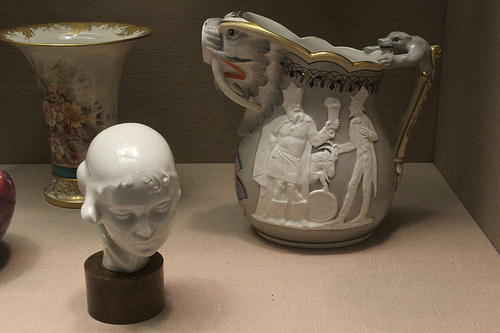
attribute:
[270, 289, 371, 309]
table — DISPLAY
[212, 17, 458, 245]
pitcher — ORNATE, LARGE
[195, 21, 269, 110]
head — ANIMAL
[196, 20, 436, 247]
vase — BLACK, GOLD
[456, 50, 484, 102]
wall — TAN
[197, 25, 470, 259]
pitcher — UNATTRACTIVE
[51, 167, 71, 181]
band — BLUE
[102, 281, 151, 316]
base — BROWN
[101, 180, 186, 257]
face — HUMAN, SCULPTURE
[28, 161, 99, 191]
stripe — blue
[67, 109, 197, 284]
statue — white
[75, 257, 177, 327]
base — cylindrical, brown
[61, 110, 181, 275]
head — white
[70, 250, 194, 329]
base — brown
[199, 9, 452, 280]
pitcher — gray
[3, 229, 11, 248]
vase — red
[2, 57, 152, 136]
vase —  white and gold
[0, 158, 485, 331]
table — tan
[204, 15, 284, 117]
head — bird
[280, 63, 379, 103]
decoration — black, gold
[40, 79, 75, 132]
flower — painted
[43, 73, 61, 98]
flower — painted